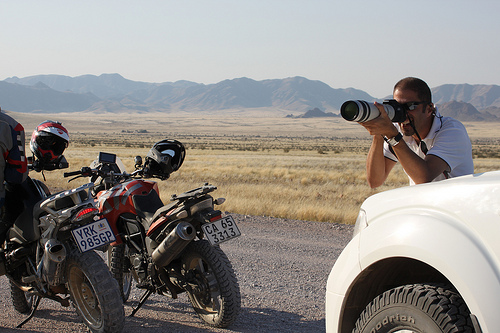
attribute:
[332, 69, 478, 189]
man — standing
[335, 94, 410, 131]
camera — white, long, black, silver, big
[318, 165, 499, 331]
car — white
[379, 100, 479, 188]
shirt — white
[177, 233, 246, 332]
tire — rubber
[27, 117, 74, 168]
helmet — red, white, silver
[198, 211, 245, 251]
license plate — black, white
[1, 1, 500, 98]
clouds — white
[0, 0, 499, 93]
sky — blue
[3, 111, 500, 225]
grass — dry, yellow